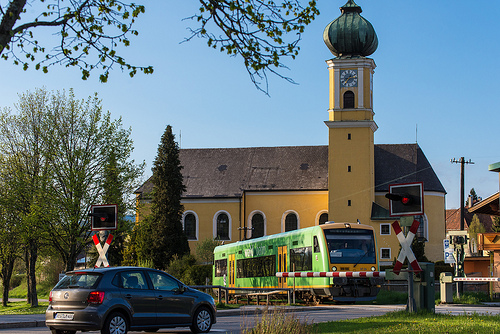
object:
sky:
[0, 0, 496, 149]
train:
[212, 222, 377, 300]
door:
[227, 253, 236, 292]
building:
[179, 144, 446, 264]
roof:
[133, 144, 418, 198]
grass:
[316, 311, 500, 333]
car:
[45, 265, 216, 331]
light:
[401, 197, 408, 204]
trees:
[143, 126, 190, 266]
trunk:
[30, 250, 38, 306]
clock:
[340, 70, 357, 87]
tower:
[324, 0, 378, 221]